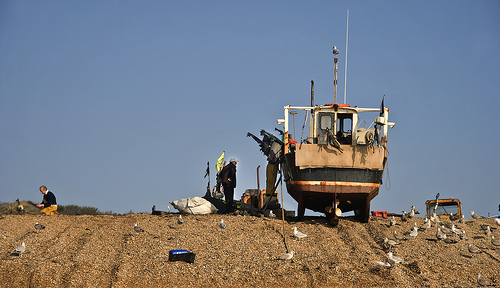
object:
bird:
[386, 251, 404, 267]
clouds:
[26, 15, 473, 165]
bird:
[491, 235, 500, 245]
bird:
[475, 272, 497, 287]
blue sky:
[0, 0, 496, 215]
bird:
[14, 241, 27, 258]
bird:
[276, 250, 295, 265]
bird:
[288, 226, 308, 241]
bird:
[382, 237, 402, 250]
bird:
[436, 227, 447, 243]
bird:
[467, 243, 483, 257]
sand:
[25, 233, 498, 281]